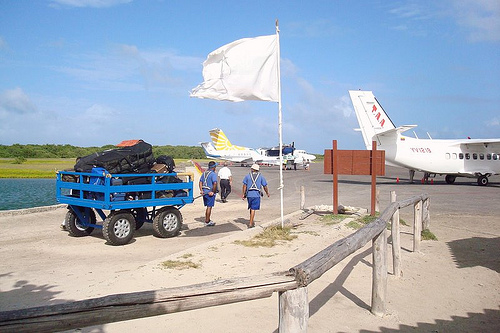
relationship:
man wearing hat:
[242, 164, 268, 229] [250, 160, 263, 171]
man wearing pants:
[217, 160, 232, 202] [217, 181, 231, 205]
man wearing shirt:
[242, 164, 268, 229] [211, 144, 248, 184]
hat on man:
[250, 162, 260, 171] [241, 162, 269, 227]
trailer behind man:
[56, 170, 193, 245] [242, 164, 268, 229]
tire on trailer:
[101, 212, 135, 244] [49, 165, 196, 241]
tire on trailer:
[150, 205, 182, 237] [49, 165, 196, 241]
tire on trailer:
[64, 204, 96, 236] [49, 165, 196, 241]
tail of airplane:
[347, 87, 399, 164] [353, 87, 500, 176]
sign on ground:
[318, 138, 394, 218] [268, 212, 427, 277]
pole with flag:
[276, 25, 283, 228] [189, 33, 285, 103]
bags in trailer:
[77, 139, 155, 170] [56, 170, 193, 245]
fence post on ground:
[351, 223, 398, 325] [2, 157, 498, 330]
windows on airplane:
[446, 151, 493, 162] [353, 87, 500, 176]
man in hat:
[242, 164, 268, 229] [250, 163, 260, 174]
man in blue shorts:
[193, 160, 221, 227] [198, 193, 216, 208]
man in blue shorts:
[242, 164, 268, 229] [243, 200, 263, 215]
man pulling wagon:
[193, 160, 221, 227] [52, 159, 194, 238]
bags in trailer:
[66, 122, 191, 189] [56, 170, 193, 245]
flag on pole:
[189, 33, 285, 103] [274, 18, 289, 227]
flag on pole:
[189, 33, 285, 103] [275, 15, 284, 227]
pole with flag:
[272, 93, 297, 231] [195, 17, 294, 114]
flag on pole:
[189, 33, 285, 103] [274, 101, 289, 227]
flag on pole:
[189, 33, 285, 103] [271, 15, 289, 231]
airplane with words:
[346, 87, 499, 188] [366, 101, 389, 131]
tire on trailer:
[150, 205, 182, 237] [56, 170, 193, 245]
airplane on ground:
[353, 87, 500, 176] [409, 173, 499, 316]